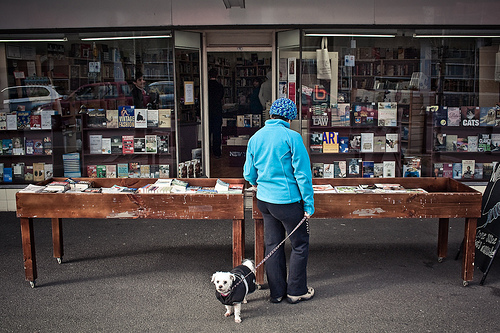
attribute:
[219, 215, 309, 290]
leash — multi-colored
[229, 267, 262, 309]
coat — black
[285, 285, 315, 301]
shoe — white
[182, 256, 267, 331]
dog — small, white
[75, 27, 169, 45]
light — on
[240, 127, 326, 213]
jacket — light blue, fleece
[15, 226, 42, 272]
leg — brown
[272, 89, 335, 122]
hat — blue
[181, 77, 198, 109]
sign — white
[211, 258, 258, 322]
dog — small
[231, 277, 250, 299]
vest — black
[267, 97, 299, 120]
hat — blue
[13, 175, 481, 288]
stands — wooden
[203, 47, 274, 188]
door — open